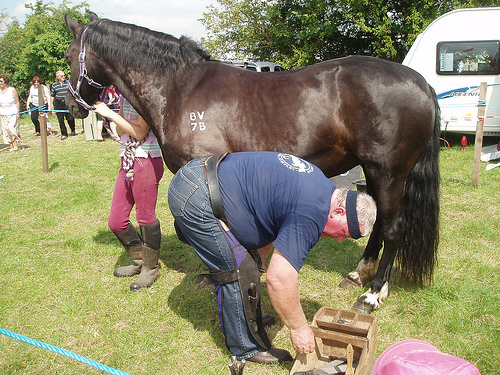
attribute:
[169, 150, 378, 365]
man — bending, hunched, bent over, old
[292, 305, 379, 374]
box — wooden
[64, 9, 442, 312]
horse — tall, brown, black, dark brown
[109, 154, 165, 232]
pants — pink, red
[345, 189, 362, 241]
sweatband — blue, black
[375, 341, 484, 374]
bag — pink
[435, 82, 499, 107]
rope — blue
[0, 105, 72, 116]
rope — blue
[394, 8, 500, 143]
trailer — white, blue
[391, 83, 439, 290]
tail — long, black, bushy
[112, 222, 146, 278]
boot — brown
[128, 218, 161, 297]
boot — brown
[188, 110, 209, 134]
letters — white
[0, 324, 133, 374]
hose — blue, green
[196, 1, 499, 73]
tree — green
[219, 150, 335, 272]
t-shirt — blue, wrinkled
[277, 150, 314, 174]
logo — white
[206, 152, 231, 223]
belt — black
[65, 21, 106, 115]
rein — pink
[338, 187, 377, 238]
hair — grey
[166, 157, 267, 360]
jeans — blue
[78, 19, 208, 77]
hair — black, long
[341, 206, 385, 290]
right foot — white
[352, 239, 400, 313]
left foot — white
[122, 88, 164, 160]
shirt — pink, striped, white, green